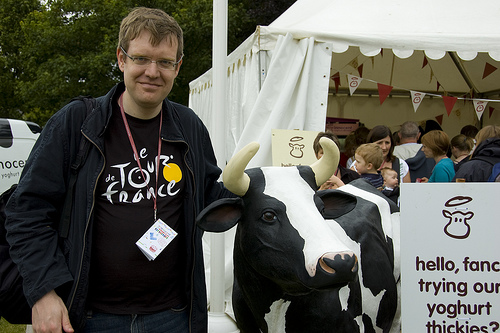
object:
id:
[135, 218, 178, 261]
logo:
[101, 148, 182, 204]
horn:
[310, 136, 341, 187]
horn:
[223, 141, 260, 196]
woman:
[421, 130, 457, 183]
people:
[312, 119, 500, 205]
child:
[381, 166, 400, 203]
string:
[332, 67, 500, 102]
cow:
[195, 136, 401, 332]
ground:
[286, 48, 300, 58]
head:
[442, 196, 474, 239]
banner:
[347, 74, 489, 121]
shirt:
[81, 94, 205, 311]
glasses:
[121, 46, 185, 70]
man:
[0, 7, 237, 333]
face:
[124, 30, 179, 104]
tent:
[188, 0, 500, 333]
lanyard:
[120, 90, 162, 210]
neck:
[121, 87, 162, 117]